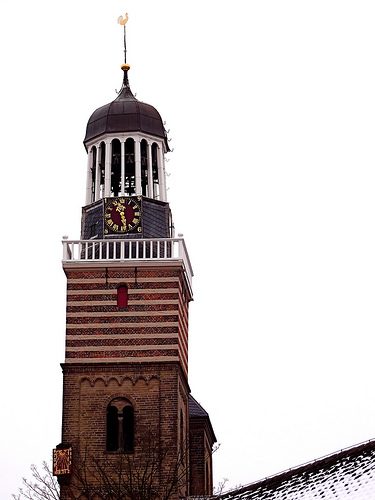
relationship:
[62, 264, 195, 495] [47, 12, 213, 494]
brick on tower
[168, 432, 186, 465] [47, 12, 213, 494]
brick on tower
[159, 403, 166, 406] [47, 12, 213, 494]
brick on tower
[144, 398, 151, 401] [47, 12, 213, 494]
brick on tower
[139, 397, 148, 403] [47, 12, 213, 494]
brick on tower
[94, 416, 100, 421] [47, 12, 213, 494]
brick on tower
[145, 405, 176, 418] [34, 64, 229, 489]
brick on tower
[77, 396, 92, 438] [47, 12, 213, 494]
brick on tower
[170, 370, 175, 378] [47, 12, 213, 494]
brick on tower